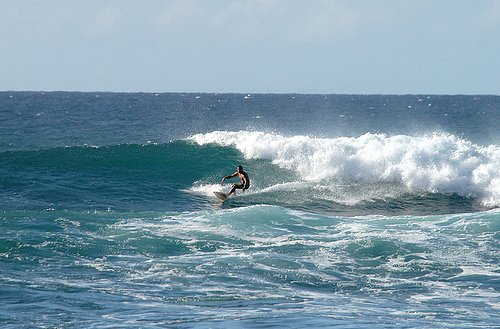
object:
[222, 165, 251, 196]
person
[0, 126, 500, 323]
waves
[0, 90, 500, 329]
ocean